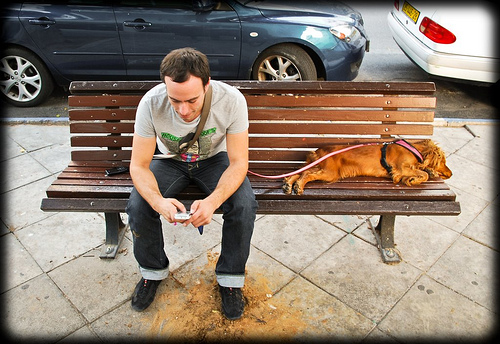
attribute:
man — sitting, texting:
[123, 48, 257, 323]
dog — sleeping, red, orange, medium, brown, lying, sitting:
[275, 137, 457, 197]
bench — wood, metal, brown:
[37, 79, 462, 219]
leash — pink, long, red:
[248, 136, 424, 179]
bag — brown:
[139, 81, 215, 160]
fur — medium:
[276, 141, 455, 196]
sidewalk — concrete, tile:
[1, 124, 499, 341]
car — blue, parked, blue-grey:
[0, 0, 381, 109]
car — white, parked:
[386, 1, 498, 100]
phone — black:
[104, 164, 130, 175]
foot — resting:
[214, 278, 247, 320]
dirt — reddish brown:
[140, 251, 306, 343]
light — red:
[416, 15, 457, 48]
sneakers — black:
[130, 269, 243, 320]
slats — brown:
[37, 76, 465, 216]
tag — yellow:
[400, 1, 422, 26]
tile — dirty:
[1, 123, 499, 344]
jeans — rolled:
[129, 151, 256, 290]